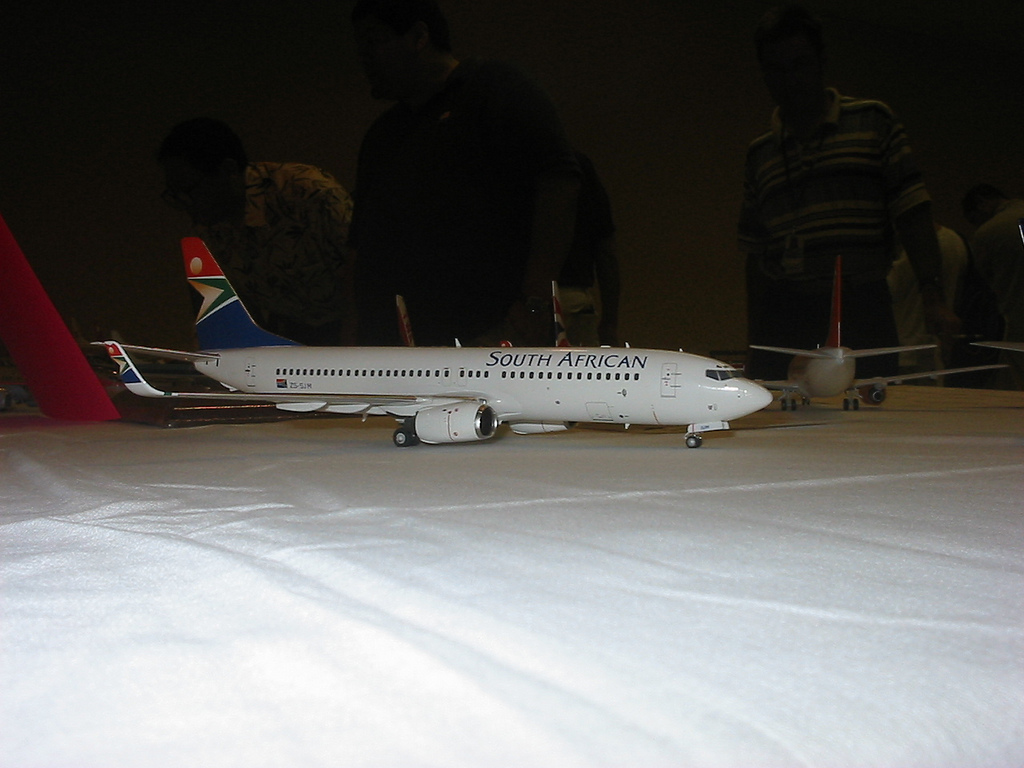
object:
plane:
[88, 236, 773, 458]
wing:
[90, 344, 369, 418]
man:
[733, 1, 966, 386]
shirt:
[729, 85, 932, 286]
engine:
[392, 399, 498, 447]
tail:
[180, 237, 308, 350]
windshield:
[679, 351, 777, 399]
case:
[0, 0, 829, 764]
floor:
[243, 438, 1024, 768]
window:
[567, 372, 639, 380]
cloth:
[0, 520, 395, 688]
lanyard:
[774, 128, 824, 218]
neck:
[761, 79, 841, 127]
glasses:
[758, 69, 827, 95]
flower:
[246, 219, 329, 275]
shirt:
[189, 155, 354, 324]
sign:
[98, 340, 145, 386]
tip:
[176, 236, 223, 279]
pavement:
[671, 448, 890, 530]